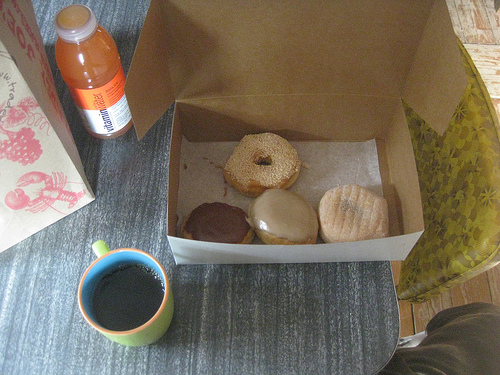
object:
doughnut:
[221, 132, 302, 197]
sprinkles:
[232, 154, 250, 169]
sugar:
[323, 213, 350, 230]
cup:
[75, 239, 176, 349]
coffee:
[96, 272, 160, 314]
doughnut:
[182, 201, 255, 245]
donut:
[245, 189, 319, 248]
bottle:
[54, 6, 133, 141]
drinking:
[53, 3, 135, 140]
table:
[1, 1, 397, 374]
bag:
[1, 1, 95, 255]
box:
[124, 1, 473, 264]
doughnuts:
[318, 181, 389, 244]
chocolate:
[194, 204, 239, 238]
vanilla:
[253, 186, 319, 242]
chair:
[391, 28, 498, 302]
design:
[476, 186, 498, 207]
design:
[2, 121, 44, 166]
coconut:
[224, 132, 300, 196]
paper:
[177, 132, 387, 243]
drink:
[75, 238, 175, 347]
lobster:
[4, 167, 89, 215]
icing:
[191, 206, 246, 243]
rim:
[107, 245, 165, 273]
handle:
[89, 240, 113, 260]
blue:
[103, 251, 145, 263]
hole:
[253, 153, 273, 166]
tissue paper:
[300, 139, 393, 185]